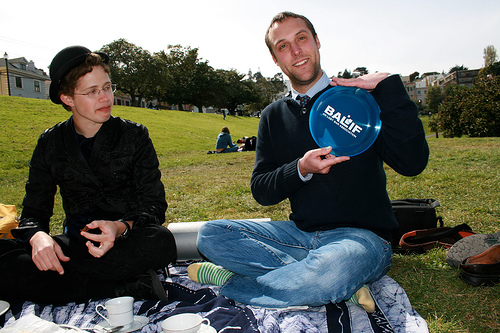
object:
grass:
[4, 96, 500, 333]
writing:
[322, 104, 363, 138]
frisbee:
[309, 86, 381, 162]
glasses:
[70, 81, 120, 101]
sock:
[187, 260, 233, 287]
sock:
[347, 284, 375, 312]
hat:
[49, 44, 113, 104]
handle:
[93, 303, 106, 323]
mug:
[95, 295, 135, 333]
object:
[79, 225, 89, 232]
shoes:
[139, 268, 167, 301]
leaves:
[145, 62, 162, 75]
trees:
[96, 37, 172, 107]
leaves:
[473, 92, 489, 111]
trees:
[481, 46, 500, 69]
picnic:
[0, 0, 500, 332]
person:
[189, 10, 430, 311]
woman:
[215, 126, 240, 154]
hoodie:
[215, 132, 234, 148]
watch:
[117, 219, 134, 240]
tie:
[295, 93, 310, 112]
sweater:
[250, 72, 431, 239]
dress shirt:
[289, 69, 333, 108]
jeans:
[197, 216, 393, 308]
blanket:
[0, 275, 416, 332]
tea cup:
[160, 313, 212, 332]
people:
[2, 45, 183, 307]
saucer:
[162, 324, 221, 332]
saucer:
[93, 313, 150, 332]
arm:
[119, 125, 168, 260]